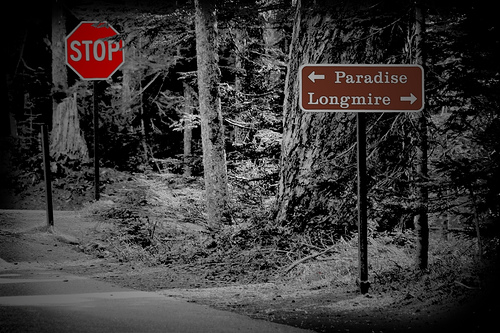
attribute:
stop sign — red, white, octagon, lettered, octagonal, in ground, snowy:
[60, 20, 127, 83]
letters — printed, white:
[68, 38, 127, 63]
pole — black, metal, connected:
[89, 80, 105, 206]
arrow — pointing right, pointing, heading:
[305, 71, 325, 83]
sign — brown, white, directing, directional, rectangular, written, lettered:
[296, 62, 424, 116]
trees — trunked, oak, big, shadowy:
[35, 4, 497, 254]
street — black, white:
[2, 199, 290, 332]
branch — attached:
[160, 89, 205, 127]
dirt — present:
[122, 252, 290, 330]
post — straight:
[352, 114, 375, 269]